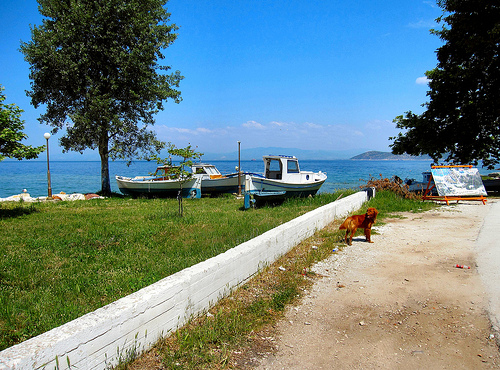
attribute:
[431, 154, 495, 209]
sign — large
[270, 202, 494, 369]
dingy ground — small , brown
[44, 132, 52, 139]
globe — white 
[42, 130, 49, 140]
light bulb — circular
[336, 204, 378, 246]
dog — Brown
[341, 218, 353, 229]
tail — long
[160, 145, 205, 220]
tree — Young 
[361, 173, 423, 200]
branch — Dead 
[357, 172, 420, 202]
leaves — brown 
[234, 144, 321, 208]
boat — blue , White 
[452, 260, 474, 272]
bottle — Plastic 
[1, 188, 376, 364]
wall — low, white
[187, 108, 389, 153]
clouds — white 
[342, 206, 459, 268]
retreiver — red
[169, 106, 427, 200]
water — large